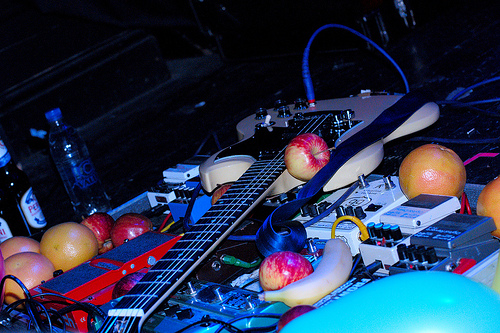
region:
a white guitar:
[133, 82, 437, 311]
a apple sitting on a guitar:
[252, 102, 339, 221]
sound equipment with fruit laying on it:
[126, 160, 467, 331]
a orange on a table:
[380, 118, 482, 233]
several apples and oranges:
[0, 187, 158, 304]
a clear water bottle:
[51, 89, 100, 224]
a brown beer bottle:
[3, 119, 58, 254]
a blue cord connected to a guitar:
[278, 34, 413, 123]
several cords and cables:
[6, 267, 108, 331]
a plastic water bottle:
[53, 86, 89, 222]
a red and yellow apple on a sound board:
[253, 248, 318, 285]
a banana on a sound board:
[256, 221, 351, 311]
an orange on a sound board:
[39, 221, 98, 263]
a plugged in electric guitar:
[112, 81, 450, 330]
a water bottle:
[42, 93, 125, 238]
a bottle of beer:
[1, 136, 53, 242]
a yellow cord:
[318, 205, 388, 247]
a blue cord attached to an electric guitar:
[285, 18, 446, 111]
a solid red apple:
[110, 206, 148, 239]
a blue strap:
[252, 71, 459, 264]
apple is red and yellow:
[283, 136, 345, 225]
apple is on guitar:
[118, 109, 341, 321]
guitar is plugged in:
[282, 52, 412, 114]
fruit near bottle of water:
[20, 210, 93, 272]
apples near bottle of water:
[75, 219, 158, 247]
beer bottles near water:
[0, 126, 31, 266]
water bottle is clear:
[31, 95, 143, 252]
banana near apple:
[265, 222, 391, 296]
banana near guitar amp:
[273, 221, 375, 286]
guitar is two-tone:
[167, 56, 394, 311]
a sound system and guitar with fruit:
[13, 12, 476, 300]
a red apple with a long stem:
[272, 134, 344, 191]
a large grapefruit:
[398, 152, 477, 210]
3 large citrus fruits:
[4, 225, 90, 302]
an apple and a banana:
[262, 243, 337, 306]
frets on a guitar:
[122, 262, 194, 319]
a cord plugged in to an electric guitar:
[280, 54, 347, 121]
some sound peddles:
[327, 183, 469, 285]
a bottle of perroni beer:
[5, 175, 62, 236]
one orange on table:
[386, 130, 463, 211]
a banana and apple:
[252, 235, 352, 315]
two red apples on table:
[87, 208, 147, 252]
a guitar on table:
[119, 82, 404, 319]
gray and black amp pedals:
[322, 188, 494, 290]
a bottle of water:
[67, 106, 107, 232]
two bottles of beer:
[0, 127, 61, 251]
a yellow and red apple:
[268, 125, 335, 201]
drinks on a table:
[0, 103, 105, 238]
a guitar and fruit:
[10, 96, 465, 328]